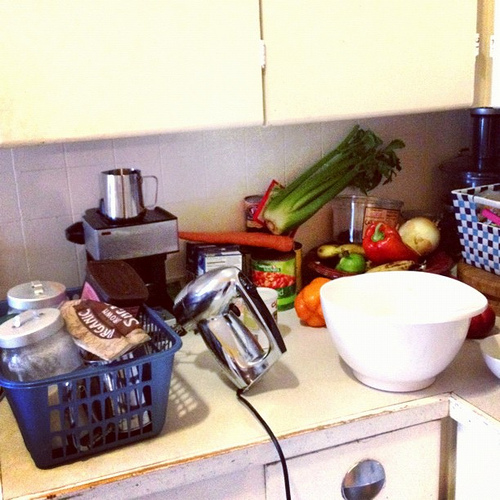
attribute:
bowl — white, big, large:
[319, 269, 490, 395]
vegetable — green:
[263, 123, 408, 235]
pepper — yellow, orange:
[294, 276, 331, 328]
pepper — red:
[362, 221, 424, 267]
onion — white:
[397, 215, 441, 255]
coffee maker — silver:
[64, 207, 182, 328]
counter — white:
[0, 285, 499, 499]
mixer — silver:
[171, 266, 288, 395]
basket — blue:
[0, 287, 183, 470]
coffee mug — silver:
[100, 167, 160, 225]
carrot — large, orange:
[176, 231, 295, 254]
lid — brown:
[85, 259, 150, 302]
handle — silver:
[340, 456, 387, 498]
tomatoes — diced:
[252, 270, 294, 288]